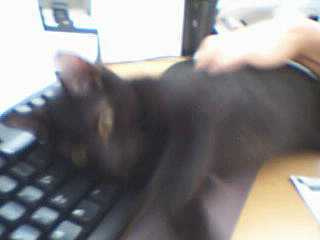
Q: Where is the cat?
A: On the desk.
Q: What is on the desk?
A: Cat.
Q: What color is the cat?
A: Black.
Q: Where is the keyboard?
A: Under the cat.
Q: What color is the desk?
A: Brown.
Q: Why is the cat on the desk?
A: Attention.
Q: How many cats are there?
A: One.